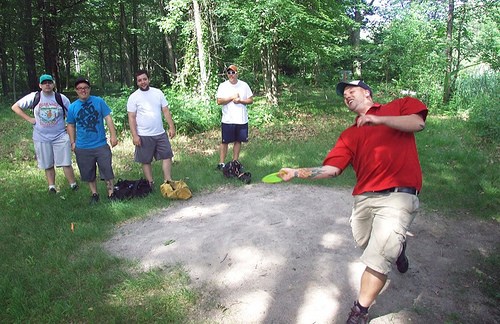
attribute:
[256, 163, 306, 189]
frisbee — neon green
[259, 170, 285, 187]
disc — green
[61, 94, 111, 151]
shirt — Blue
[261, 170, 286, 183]
frisbee — green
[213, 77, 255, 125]
tee shirt — white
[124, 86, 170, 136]
tee shirt — white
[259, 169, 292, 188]
disc — flying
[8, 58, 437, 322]
people — playing disc golf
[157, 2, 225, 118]
tree — green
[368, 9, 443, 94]
tree — green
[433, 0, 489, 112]
tree — green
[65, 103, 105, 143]
shirt — blue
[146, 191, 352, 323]
ground — light grey, starting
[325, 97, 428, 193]
polo — red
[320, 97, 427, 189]
shirt — red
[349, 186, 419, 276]
shorts — grey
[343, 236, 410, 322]
shoes — black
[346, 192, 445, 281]
shorts — white, cargo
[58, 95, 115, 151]
shirt — black, blue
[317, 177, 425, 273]
shorts — khaki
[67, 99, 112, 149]
tee shirt — blue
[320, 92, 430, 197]
shirt — red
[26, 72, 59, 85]
blue cap — bright blue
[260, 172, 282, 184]
disk — neon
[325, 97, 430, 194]
shirt — red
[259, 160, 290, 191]
frisbee — green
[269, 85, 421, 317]
he — standing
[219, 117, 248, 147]
shorts — blue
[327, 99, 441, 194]
shirt — red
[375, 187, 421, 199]
belt — black